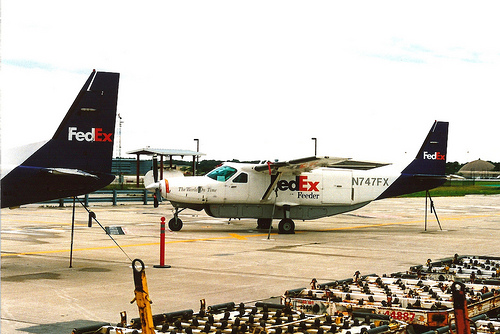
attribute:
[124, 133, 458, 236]
plane — white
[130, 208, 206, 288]
stand — safety